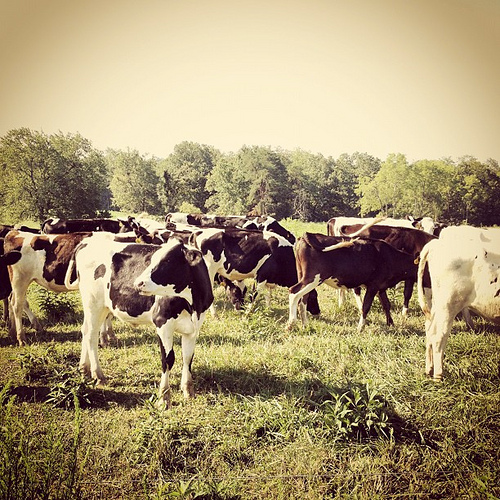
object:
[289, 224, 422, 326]
cows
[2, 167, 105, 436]
field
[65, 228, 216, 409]
cow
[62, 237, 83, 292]
tail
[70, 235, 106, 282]
rear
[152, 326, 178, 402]
leg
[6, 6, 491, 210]
background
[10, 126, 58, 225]
trees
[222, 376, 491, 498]
grass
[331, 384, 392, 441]
weeds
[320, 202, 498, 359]
group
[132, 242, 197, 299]
head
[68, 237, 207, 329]
body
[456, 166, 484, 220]
shrubs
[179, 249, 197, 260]
tag